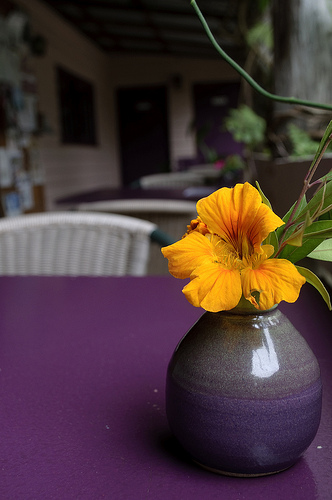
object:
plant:
[158, 111, 332, 315]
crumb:
[153, 386, 161, 394]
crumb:
[314, 445, 322, 448]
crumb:
[106, 423, 110, 430]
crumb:
[156, 406, 162, 412]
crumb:
[152, 401, 159, 409]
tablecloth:
[57, 199, 196, 209]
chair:
[136, 169, 209, 189]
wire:
[189, 4, 322, 105]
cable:
[190, 0, 332, 111]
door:
[112, 81, 170, 186]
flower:
[161, 180, 306, 314]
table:
[68, 198, 198, 208]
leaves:
[256, 119, 332, 313]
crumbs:
[151, 387, 159, 411]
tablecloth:
[1, 268, 332, 500]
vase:
[162, 296, 324, 484]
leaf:
[256, 171, 332, 266]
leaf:
[288, 264, 332, 311]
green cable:
[189, 0, 332, 113]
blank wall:
[57, 151, 99, 187]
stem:
[186, 0, 330, 107]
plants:
[186, 0, 332, 182]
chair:
[1, 207, 175, 274]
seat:
[0, 211, 176, 276]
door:
[187, 78, 242, 159]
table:
[0, 275, 332, 500]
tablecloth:
[55, 194, 210, 216]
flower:
[212, 155, 226, 171]